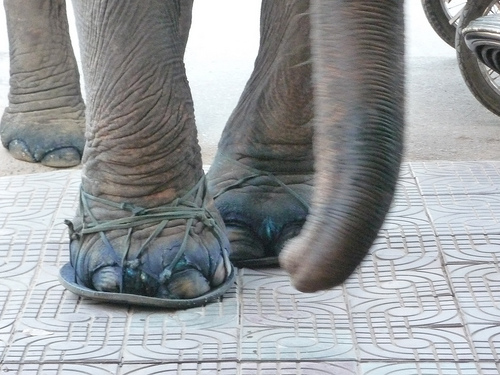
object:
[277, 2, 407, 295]
trunk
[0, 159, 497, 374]
designs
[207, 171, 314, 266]
foot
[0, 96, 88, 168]
feet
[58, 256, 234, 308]
shoe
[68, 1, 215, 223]
leg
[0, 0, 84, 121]
leg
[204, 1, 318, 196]
leg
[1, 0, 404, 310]
elephant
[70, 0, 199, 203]
elephant's skin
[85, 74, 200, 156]
knee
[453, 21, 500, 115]
wheel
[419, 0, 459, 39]
wheel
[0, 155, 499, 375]
sidewalk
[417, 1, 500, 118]
bike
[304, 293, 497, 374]
ground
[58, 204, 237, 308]
feet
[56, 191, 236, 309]
shoes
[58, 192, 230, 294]
strings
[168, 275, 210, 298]
nail